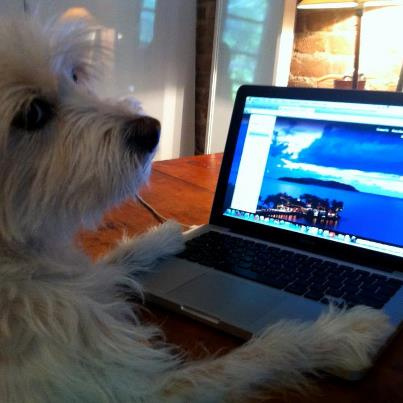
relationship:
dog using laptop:
[2, 8, 387, 400] [120, 85, 402, 353]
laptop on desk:
[120, 85, 402, 353] [30, 149, 401, 395]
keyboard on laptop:
[191, 251, 364, 272] [137, 66, 363, 350]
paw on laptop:
[309, 301, 393, 372] [120, 85, 402, 353]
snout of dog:
[111, 109, 163, 172] [2, 8, 387, 400]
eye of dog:
[16, 97, 49, 130] [2, 8, 387, 400]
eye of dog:
[16, 94, 58, 133] [8, 28, 119, 336]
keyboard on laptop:
[171, 227, 402, 310] [239, 93, 387, 301]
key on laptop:
[203, 231, 265, 264] [180, 70, 399, 334]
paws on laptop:
[305, 323, 375, 364] [216, 91, 388, 296]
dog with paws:
[2, 8, 387, 400] [305, 323, 375, 364]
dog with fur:
[17, 60, 174, 363] [26, 144, 90, 210]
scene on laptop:
[280, 137, 392, 199] [202, 59, 396, 395]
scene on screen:
[280, 137, 392, 199] [253, 109, 394, 222]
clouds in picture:
[276, 118, 402, 196] [292, 138, 394, 193]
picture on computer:
[292, 138, 394, 193] [111, 82, 401, 372]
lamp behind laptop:
[293, 0, 401, 86] [120, 85, 402, 353]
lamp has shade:
[293, 0, 401, 86] [291, 2, 399, 12]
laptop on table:
[120, 85, 402, 353] [61, 137, 395, 379]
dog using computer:
[2, 8, 387, 400] [111, 82, 401, 372]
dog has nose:
[2, 8, 387, 400] [120, 107, 167, 157]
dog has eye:
[8, 55, 174, 308] [11, 90, 62, 151]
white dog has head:
[0, 12, 388, 402] [0, 0, 161, 243]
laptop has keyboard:
[97, 54, 402, 352] [171, 227, 402, 310]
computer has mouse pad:
[111, 82, 401, 372] [164, 265, 285, 324]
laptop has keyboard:
[120, 85, 402, 353] [170, 214, 400, 311]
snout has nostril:
[111, 109, 163, 172] [126, 131, 152, 154]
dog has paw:
[2, 8, 387, 400] [121, 216, 190, 268]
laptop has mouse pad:
[120, 85, 402, 353] [162, 268, 288, 328]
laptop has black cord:
[120, 85, 402, 353] [134, 190, 187, 227]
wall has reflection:
[14, 1, 195, 170] [47, 5, 118, 79]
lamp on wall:
[293, 0, 401, 86] [286, 0, 401, 93]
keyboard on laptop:
[171, 227, 402, 310] [120, 85, 402, 353]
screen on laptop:
[223, 91, 402, 256] [118, 83, 402, 382]